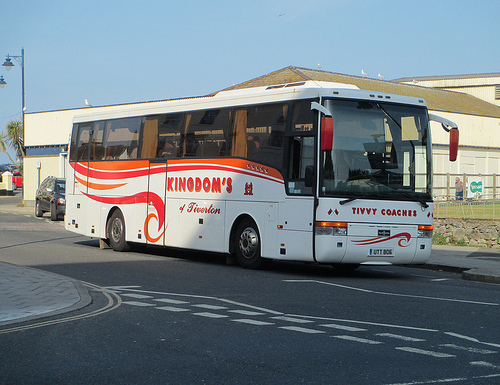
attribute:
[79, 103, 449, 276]
bus — close, large, red, coach, big, orange, traveling, driving, white, massive, moving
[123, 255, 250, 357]
road — paved, smooth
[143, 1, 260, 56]
sky — clear, blue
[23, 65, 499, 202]
building — white